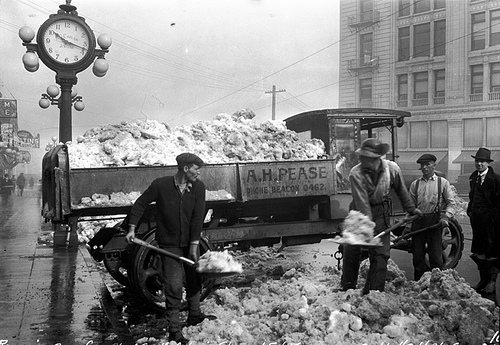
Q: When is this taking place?
A: In the 19th century.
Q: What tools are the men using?
A: Shovels.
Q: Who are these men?
A: Laborers.